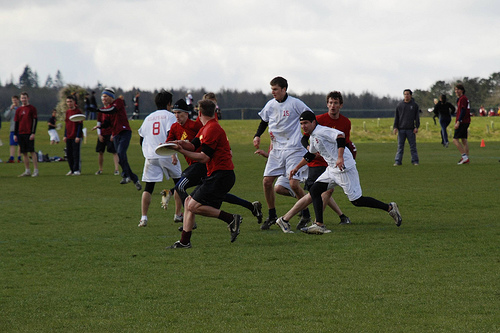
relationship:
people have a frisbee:
[138, 75, 404, 250] [157, 142, 180, 156]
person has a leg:
[171, 99, 241, 249] [185, 178, 240, 245]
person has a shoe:
[171, 99, 241, 249] [228, 212, 242, 243]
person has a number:
[137, 90, 189, 226] [150, 123, 161, 135]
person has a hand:
[171, 99, 241, 249] [173, 146, 184, 155]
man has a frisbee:
[288, 111, 403, 231] [157, 142, 180, 156]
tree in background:
[18, 67, 41, 88] [1, 2, 499, 121]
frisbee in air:
[157, 142, 180, 156] [1, 3, 499, 332]